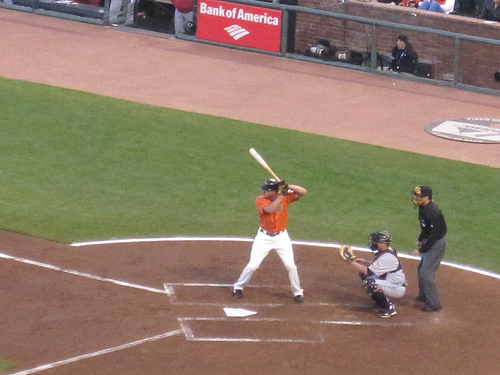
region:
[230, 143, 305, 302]
a batter wearing an orange shirt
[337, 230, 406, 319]
a crouching catcher in catcher's gear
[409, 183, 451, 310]
an umpire in mask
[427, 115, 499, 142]
an advertising sign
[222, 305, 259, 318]
a bright white home plate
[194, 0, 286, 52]
a red and white Bank of America sign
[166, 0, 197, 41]
the lower half of a man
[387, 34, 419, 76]
the torso of a man in black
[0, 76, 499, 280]
a swatch of green grass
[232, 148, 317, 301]
man standing on field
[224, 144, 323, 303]
man holding baseball bat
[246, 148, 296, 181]
brown wooden baseball bat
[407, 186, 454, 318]
umpire standing on base ball field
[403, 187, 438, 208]
brown and black umpire mask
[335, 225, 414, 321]
catcher on base ball field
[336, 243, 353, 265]
brown and black catchers mit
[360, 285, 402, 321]
black shin guards on catcher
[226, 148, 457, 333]
group of men playing baseball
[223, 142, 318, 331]
man at home plate about to swing bat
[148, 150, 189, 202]
part of a field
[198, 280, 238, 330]
part of a linje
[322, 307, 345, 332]
part of a geround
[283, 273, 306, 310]
part of as hoe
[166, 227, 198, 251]
edge of a loine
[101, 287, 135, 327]
part of a grounmd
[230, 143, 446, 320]
the men on the baseball field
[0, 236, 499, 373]
the white lines on the baseball field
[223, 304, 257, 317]
the white home plate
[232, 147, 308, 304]
the batter up to bat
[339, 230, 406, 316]
the catcher crouching down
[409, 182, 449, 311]
the umpire behind the catcher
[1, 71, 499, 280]
the green grass on the field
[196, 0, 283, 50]
the red banner on the fence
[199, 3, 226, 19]
the word "Bank" on the red banner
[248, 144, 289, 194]
the bat in the batter's hands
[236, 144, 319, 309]
man with baseball bat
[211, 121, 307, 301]
man up to bat in orange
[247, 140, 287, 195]
baseball bat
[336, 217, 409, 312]
catcher ready for a ball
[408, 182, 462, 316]
man in black shirt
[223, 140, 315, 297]
man in orange shirt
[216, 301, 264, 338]
home base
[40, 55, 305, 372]
baseball field with batter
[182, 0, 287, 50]
bank of america avertisement on a fence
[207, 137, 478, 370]
three men playing baseball